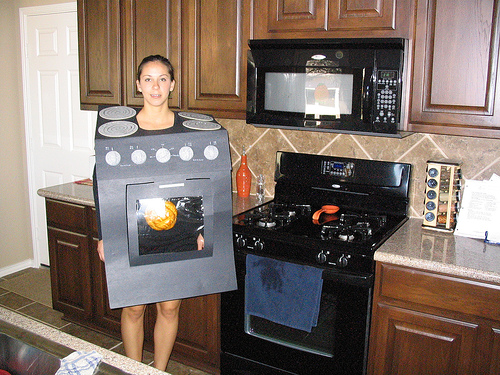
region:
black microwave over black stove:
[228, 30, 412, 138]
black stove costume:
[74, 99, 254, 321]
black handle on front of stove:
[238, 248, 378, 293]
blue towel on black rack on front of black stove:
[236, 248, 326, 338]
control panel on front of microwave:
[366, 68, 402, 128]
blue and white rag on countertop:
[44, 341, 106, 373]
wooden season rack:
[416, 156, 475, 240]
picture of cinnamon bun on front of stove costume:
[140, 200, 191, 236]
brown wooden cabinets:
[73, 1, 248, 119]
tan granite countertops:
[372, 208, 497, 289]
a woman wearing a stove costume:
[96, 54, 241, 371]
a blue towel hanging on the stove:
[242, 252, 328, 336]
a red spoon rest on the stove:
[314, 204, 338, 224]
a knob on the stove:
[315, 251, 330, 263]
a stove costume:
[96, 103, 241, 310]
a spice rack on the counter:
[421, 157, 459, 234]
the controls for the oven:
[321, 158, 356, 180]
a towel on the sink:
[51, 349, 101, 373]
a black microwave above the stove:
[246, 35, 409, 136]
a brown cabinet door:
[45, 225, 94, 322]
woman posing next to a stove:
[93, 53, 410, 371]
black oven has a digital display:
[319, 156, 356, 181]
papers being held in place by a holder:
[451, 170, 497, 242]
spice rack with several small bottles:
[420, 156, 461, 231]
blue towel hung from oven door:
[240, 253, 322, 333]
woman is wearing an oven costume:
[95, 55, 240, 306]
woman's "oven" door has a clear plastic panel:
[125, 176, 216, 266]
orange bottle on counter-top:
[233, 150, 250, 200]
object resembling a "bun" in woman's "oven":
[141, 196, 177, 231]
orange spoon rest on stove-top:
[310, 201, 340, 226]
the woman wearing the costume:
[93, 52, 224, 369]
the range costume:
[78, 64, 253, 309]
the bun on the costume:
[133, 199, 188, 231]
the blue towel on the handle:
[238, 246, 318, 331]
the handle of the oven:
[231, 245, 366, 290]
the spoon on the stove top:
[300, 200, 340, 220]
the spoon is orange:
[300, 196, 345, 221]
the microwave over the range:
[240, 36, 400, 131]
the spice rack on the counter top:
[410, 151, 467, 236]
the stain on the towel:
[255, 255, 286, 290]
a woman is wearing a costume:
[86, 57, 237, 306]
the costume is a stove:
[97, 95, 237, 307]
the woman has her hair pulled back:
[136, 56, 173, 104]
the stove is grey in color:
[94, 103, 235, 310]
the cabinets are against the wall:
[73, 0, 498, 142]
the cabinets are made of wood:
[73, 3, 498, 148]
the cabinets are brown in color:
[72, 2, 496, 143]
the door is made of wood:
[15, 3, 112, 268]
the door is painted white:
[18, 1, 92, 271]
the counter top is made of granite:
[40, 160, 497, 293]